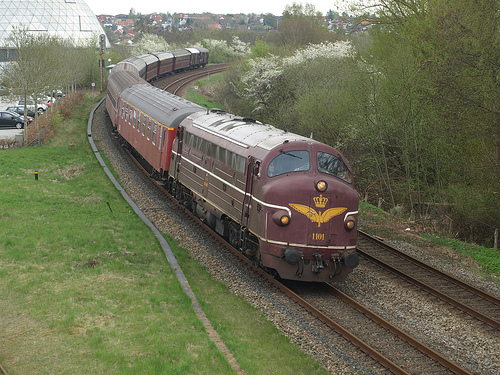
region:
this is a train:
[77, 35, 451, 362]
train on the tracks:
[109, 22, 479, 373]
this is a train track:
[269, 241, 463, 373]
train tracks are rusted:
[294, 282, 445, 374]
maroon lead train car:
[166, 72, 365, 299]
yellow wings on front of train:
[280, 197, 357, 237]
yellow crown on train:
[305, 182, 335, 212]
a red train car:
[103, 75, 205, 172]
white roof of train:
[175, 105, 307, 170]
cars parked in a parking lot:
[0, 70, 62, 151]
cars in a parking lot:
[2, 87, 52, 137]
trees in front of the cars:
[15, 35, 85, 160]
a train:
[115, 41, 362, 276]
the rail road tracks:
[281, 275, 458, 374]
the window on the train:
[270, 140, 310, 171]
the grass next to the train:
[10, 160, 211, 370]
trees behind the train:
[250, 40, 485, 165]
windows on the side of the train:
[115, 105, 160, 135]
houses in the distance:
[110, 12, 285, 38]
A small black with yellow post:
[29, 163, 43, 182]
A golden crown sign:
[308, 190, 334, 207]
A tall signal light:
[91, 32, 111, 95]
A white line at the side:
[229, 182, 291, 217]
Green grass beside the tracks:
[203, 285, 244, 330]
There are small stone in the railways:
[399, 292, 435, 334]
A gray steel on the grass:
[93, 157, 127, 190]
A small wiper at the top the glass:
[275, 145, 308, 162]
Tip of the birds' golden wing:
[285, 198, 299, 210]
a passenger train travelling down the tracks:
[86, 32, 376, 295]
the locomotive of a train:
[176, 103, 369, 278]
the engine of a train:
[195, 95, 365, 291]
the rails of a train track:
[317, 278, 493, 369]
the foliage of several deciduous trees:
[376, 5, 497, 218]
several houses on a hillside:
[105, 5, 206, 35]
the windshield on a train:
[310, 148, 353, 184]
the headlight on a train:
[273, 210, 295, 229]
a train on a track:
[103, 36, 343, 282]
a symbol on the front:
[285, 190, 350, 235]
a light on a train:
[270, 210, 295, 225]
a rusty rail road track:
[315, 287, 397, 357]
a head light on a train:
[316, 180, 327, 191]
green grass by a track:
[20, 118, 116, 365]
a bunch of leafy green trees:
[397, 0, 492, 211]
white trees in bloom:
[243, 25, 364, 105]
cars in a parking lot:
[7, 72, 59, 135]